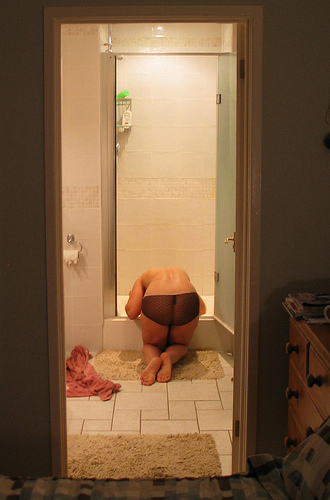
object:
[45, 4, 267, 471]
door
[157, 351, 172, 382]
feet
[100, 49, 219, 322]
shower stall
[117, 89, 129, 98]
products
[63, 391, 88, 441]
bathroom floor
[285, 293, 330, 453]
dresser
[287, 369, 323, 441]
drawer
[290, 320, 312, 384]
drawer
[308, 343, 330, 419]
drawer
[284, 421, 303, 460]
drawer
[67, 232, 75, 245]
dispenser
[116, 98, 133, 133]
rack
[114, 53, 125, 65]
shower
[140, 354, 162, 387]
foot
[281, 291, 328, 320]
book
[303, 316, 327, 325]
book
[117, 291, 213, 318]
tub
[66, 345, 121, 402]
garment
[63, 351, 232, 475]
ground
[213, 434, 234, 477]
floor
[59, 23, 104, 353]
wall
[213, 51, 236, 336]
shower door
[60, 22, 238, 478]
bathroom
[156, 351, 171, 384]
foot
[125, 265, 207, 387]
lady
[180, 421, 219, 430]
floor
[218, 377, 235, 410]
floor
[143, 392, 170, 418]
floor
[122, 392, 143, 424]
floor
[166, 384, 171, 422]
lines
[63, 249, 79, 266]
paper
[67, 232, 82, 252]
roll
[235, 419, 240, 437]
hinge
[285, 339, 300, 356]
knob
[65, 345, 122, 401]
towel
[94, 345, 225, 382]
rug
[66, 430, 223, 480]
rug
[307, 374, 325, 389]
knob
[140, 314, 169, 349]
legs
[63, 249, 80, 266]
tissue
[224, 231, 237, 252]
handle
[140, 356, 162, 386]
feet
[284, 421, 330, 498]
pillow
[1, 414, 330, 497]
bed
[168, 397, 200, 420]
tile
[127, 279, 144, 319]
arm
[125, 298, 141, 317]
elbow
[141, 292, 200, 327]
panties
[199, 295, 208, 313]
elbow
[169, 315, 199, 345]
thighs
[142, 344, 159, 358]
calves